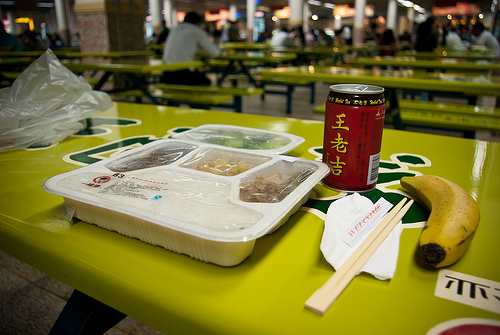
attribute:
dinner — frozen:
[56, 125, 321, 233]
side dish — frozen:
[188, 125, 289, 150]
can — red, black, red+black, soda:
[320, 79, 389, 194]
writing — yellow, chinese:
[322, 93, 388, 185]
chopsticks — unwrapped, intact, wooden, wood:
[301, 195, 418, 318]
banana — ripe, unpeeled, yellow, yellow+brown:
[397, 170, 486, 276]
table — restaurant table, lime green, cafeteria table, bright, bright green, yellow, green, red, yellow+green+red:
[2, 97, 499, 334]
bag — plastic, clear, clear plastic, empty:
[1, 44, 118, 155]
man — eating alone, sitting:
[159, 9, 226, 89]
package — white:
[41, 122, 415, 321]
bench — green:
[310, 89, 499, 135]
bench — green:
[0, 71, 268, 108]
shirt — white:
[159, 22, 227, 67]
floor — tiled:
[2, 57, 499, 334]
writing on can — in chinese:
[326, 93, 384, 180]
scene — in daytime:
[1, 1, 498, 334]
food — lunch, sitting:
[39, 78, 485, 334]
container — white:
[38, 120, 337, 269]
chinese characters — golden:
[325, 109, 354, 183]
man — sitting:
[468, 20, 499, 52]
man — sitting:
[441, 25, 470, 53]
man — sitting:
[268, 25, 295, 48]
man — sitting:
[0, 20, 29, 57]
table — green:
[147, 47, 306, 101]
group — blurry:
[0, 1, 499, 54]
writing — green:
[20, 108, 441, 251]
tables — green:
[394, 40, 499, 59]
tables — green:
[222, 40, 383, 57]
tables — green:
[0, 47, 88, 63]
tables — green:
[143, 39, 274, 51]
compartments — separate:
[43, 123, 331, 270]